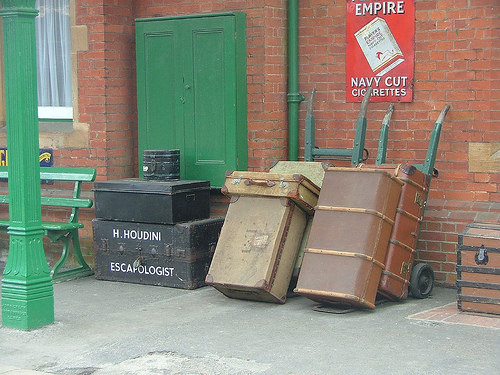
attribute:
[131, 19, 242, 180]
doors — green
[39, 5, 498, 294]
building — brick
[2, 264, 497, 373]
sidewalk — concrete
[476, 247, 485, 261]
lock — metal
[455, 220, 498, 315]
case — green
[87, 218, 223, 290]
black case — black 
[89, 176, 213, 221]
black case — black 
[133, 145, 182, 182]
black case — black 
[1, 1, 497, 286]
wall — brick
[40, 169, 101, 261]
bench — green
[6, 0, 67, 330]
lamppost — old fashioned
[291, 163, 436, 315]
luggage — heavy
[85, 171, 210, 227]
case — black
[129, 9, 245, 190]
cabinet — green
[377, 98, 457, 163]
hand truck — green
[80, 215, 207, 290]
trunk — black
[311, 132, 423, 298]
cases — green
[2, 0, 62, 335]
pole — green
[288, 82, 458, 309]
trunks — heavy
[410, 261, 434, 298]
handtruck wheel — black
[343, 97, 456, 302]
cart — green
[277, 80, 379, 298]
cart — green